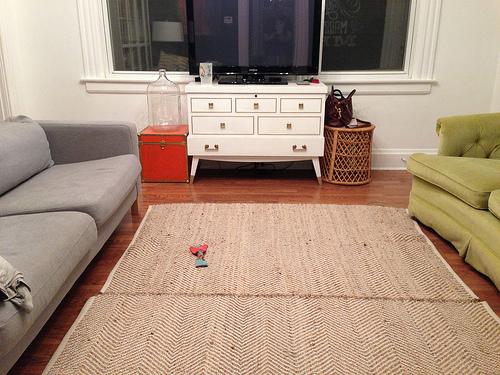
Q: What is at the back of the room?
A: Window.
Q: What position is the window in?
A: Closed.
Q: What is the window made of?
A: Glass.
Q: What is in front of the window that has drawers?
A: Dresser.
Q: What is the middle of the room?
A: Rug.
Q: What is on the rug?
A: Dog toy.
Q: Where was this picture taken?
A: Inside house.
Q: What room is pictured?
A: Living room.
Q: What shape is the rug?
A: Rectangle.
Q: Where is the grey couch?
A: On left side.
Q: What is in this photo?
A: Two couches facing each other.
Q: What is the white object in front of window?
A: White chest of drawers.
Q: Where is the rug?
A: On the floor.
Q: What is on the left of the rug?
A: A sofa.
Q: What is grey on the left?
A: The sofa.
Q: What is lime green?
A: The other sofa.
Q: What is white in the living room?
A: Dresser.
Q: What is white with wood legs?
A: Gray couch.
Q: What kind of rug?
A: Burlap.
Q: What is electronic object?
A: Television.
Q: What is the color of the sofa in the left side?
A: Grey.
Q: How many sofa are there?
A: 2.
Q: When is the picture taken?
A: Night time.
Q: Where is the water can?
A: Top of the box.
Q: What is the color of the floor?
A: Brown.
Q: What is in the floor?
A: Rug.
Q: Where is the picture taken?
A: In a living room.